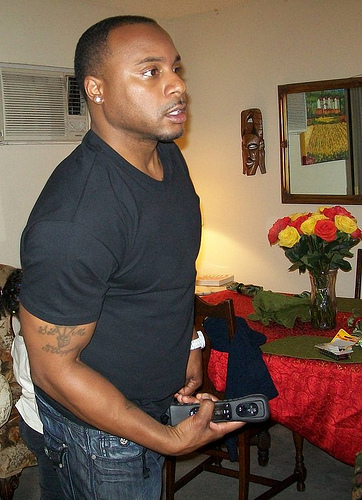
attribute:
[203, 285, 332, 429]
table cloth — red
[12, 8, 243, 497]
man — standing up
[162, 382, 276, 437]
wii remote — black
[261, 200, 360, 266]
roses — colorful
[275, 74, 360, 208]
mirror — small, rectangular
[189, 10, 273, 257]
wall — light colored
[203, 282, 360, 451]
table — red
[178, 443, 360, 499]
flooring — dark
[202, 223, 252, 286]
light — on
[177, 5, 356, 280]
wall — light colore